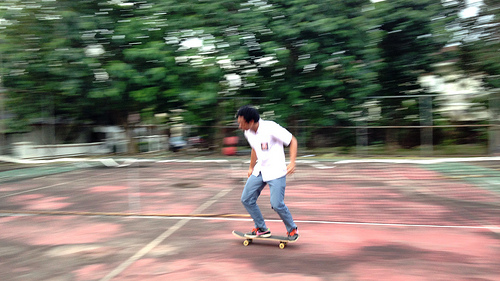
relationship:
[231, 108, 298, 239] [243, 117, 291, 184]
man has shirt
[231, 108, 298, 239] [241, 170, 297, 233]
man has pants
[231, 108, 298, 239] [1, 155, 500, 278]
man skateboarding on tennis court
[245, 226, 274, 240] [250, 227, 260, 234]
shoe has laces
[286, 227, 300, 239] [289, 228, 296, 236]
shoe has laces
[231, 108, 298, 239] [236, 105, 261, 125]
man has hair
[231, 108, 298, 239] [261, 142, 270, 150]
man has logo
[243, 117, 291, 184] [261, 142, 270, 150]
shirt has logo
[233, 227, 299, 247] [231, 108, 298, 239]
skateboard under man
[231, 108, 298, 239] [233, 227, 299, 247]
man on top of skateboard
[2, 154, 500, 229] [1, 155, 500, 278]
tennis net on top of tennis court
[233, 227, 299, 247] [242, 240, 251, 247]
skateboard has wheel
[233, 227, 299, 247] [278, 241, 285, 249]
skateboard has wheel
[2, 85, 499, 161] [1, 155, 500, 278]
wire fence around tennis court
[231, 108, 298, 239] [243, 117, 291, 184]
man wearing shirt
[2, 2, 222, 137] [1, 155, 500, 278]
tree around tennis court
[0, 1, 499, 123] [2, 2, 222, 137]
sky visible through tree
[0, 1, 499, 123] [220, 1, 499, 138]
sky visible through tree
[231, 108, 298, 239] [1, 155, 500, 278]
man skating on tennis court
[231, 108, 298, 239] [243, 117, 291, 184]
man wears shirt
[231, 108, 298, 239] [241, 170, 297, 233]
man wears pants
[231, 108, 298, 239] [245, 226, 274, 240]
man wears shoe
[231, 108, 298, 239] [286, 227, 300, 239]
man wears shoe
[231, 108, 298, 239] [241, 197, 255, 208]
man has knee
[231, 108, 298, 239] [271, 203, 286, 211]
man has knee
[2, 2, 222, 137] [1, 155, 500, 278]
tree behind tennis court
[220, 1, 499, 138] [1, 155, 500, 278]
tree behind tennis court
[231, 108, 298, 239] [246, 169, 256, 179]
man has hand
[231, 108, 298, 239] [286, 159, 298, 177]
man has hand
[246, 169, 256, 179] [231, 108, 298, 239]
hand on side of man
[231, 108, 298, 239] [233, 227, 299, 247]
man riding skateboard